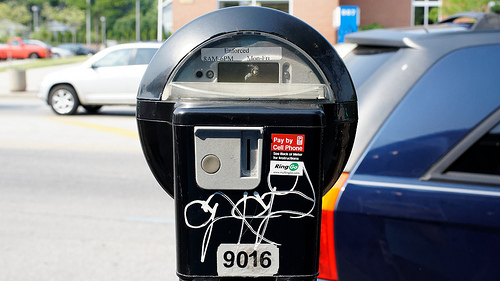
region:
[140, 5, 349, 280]
a parking meter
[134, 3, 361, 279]
a black parking meter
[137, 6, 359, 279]
meter number 9016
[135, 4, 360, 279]
graffiti on a parking meter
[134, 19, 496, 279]
a blue car parked next to a meter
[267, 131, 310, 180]
the meter has an option to pay by cellphone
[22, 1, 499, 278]
a street with paid parking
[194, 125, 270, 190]
a coin slot on a parking meter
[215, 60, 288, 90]
the parking meter has a digital display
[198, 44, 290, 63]
the parking tolls are enforced monday through friday from 8am-6pm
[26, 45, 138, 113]
this is a car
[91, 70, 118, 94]
the car is white in color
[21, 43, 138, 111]
the car is parked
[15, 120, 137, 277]
this is the road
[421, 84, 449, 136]
the car is blue in color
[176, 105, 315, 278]
this is a parking tollbooth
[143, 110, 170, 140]
the tollbooth is black in color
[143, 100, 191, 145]
the tollbooth is metallic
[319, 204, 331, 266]
this is the car's hindlight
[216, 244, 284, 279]
this is a four-digit number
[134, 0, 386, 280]
meter is black and painted on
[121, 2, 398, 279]
meter is black and painted on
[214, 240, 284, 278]
the meter number is 9016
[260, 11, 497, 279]
the car beside the meter is blue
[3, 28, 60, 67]
a red car in the background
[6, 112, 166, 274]
the road is gray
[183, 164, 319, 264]
the meter has graffiti on it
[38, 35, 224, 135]
the car behind the meter is white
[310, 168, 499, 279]
the blue car has a red tail light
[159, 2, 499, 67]
the building is brown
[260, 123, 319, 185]
the parking meter has a small sign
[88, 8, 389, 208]
black circle of top of parking meter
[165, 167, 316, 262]
white and stringy graffiti on meter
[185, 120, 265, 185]
coin slot with button to side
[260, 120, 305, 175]
sticker regarding alternate way to pay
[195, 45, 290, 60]
label giving times when payment necessaary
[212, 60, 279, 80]
dark panel with white smudge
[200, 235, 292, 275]
four-number identification of meter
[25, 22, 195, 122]
white car passing back of meter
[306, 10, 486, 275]
blue car parked by meter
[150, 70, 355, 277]
metal box supporting top of meter